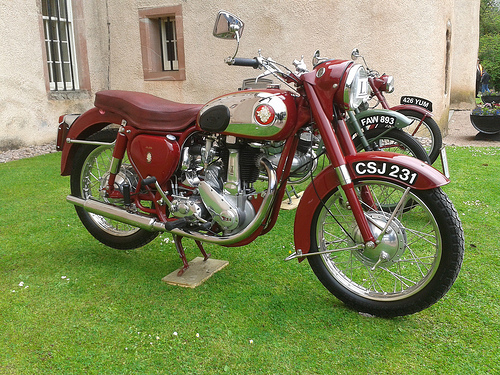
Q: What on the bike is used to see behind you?
A: Mirrors.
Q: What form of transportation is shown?
A: Motorcycles.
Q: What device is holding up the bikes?
A: Kickstands.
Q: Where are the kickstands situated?
A: On wooden blocks.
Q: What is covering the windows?
A: Metal grates.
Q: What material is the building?
A: Stone.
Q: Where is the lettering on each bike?
A: The front fender.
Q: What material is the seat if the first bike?
A: Leather.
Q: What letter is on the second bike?
A: FAW.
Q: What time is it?
A: Afternoon.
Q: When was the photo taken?
A: During daytime.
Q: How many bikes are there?
A: 3.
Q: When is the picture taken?
A: Daytime.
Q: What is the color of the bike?
A: Red.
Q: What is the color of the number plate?
A: Black and white.